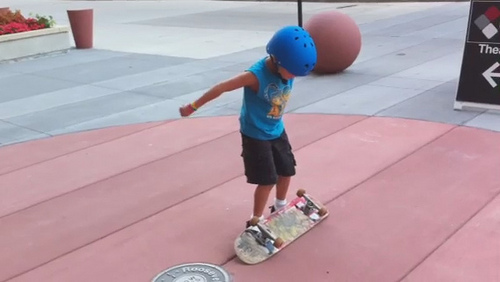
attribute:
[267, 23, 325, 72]
helmet — blue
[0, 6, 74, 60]
bed — of flowers